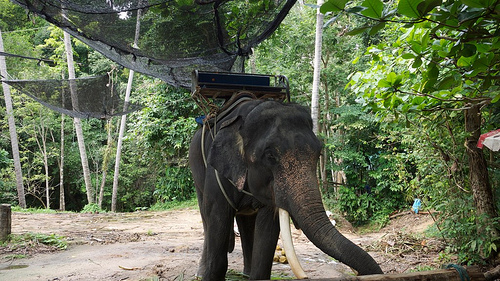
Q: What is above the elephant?
A: Mesh hamper.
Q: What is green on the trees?
A: Leaves.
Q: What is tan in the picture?
A: The ground.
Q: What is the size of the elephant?
A: Large.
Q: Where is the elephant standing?
A: In the forest.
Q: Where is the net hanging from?
A: A tree.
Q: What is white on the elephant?
A: Tusks.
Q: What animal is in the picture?
A: Elephant.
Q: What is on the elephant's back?
A: Chair.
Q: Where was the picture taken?
A: Jungle.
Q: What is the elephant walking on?
A: Ground.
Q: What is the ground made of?
A: Dirt.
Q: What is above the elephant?
A: Net.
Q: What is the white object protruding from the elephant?
A: Tusk.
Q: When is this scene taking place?
A: Daytime.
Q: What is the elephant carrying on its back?
A: Chair.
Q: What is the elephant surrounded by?
A: Foliage.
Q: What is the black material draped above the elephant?
A: Netting.